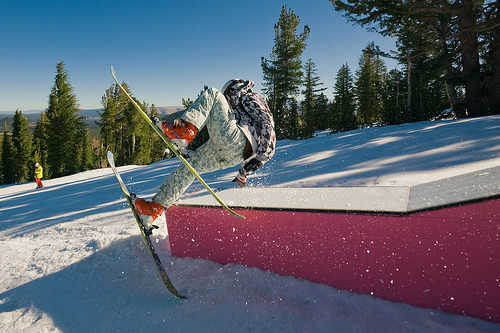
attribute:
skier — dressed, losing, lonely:
[31, 161, 49, 191]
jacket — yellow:
[35, 166, 44, 181]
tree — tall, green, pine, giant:
[260, 4, 314, 140]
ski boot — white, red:
[153, 114, 203, 152]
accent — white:
[185, 130, 195, 136]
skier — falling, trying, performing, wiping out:
[101, 65, 279, 308]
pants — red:
[35, 177, 45, 188]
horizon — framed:
[9, 116, 496, 120]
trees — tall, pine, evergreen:
[5, 73, 171, 166]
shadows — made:
[17, 169, 155, 226]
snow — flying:
[5, 123, 499, 333]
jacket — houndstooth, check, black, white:
[224, 86, 283, 187]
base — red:
[168, 216, 491, 308]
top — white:
[179, 163, 499, 209]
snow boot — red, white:
[131, 195, 168, 230]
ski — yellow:
[109, 65, 245, 219]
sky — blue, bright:
[2, 0, 405, 105]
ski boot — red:
[127, 191, 167, 233]